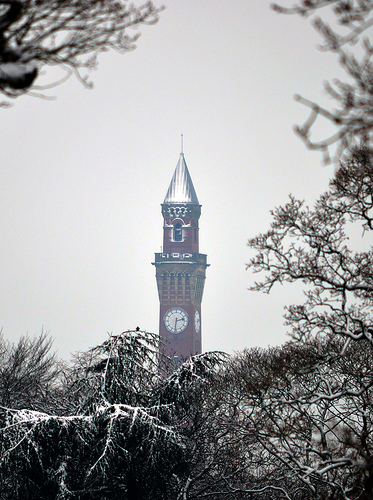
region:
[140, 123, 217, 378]
tall brick building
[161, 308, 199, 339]
two clocks on brick building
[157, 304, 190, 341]
clock on front of building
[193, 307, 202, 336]
clock on side of building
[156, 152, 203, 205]
spire of tall building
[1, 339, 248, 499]
snow covered branches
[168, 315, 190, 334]
hands of clock on front of building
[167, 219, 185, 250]
window on top of building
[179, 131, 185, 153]
bar sticking up from top of building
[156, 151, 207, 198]
snow covered roof of building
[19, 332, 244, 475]
Snow covering the trees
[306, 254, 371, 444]
Snow covering the trees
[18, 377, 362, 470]
Snow covering tree branches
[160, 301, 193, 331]
Clock on the tower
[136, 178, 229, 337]
Large brick tower with snow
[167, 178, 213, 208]
Snow covering the roof of the tower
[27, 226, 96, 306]
The sky is cloudy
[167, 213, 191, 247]
Very large window on tower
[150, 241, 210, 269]
Black balcony on the tower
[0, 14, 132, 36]
Snow covering tree branches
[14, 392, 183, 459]
White snow on some branches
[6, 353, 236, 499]
Some branchs of some trees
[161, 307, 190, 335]
A round and white clock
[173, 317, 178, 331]
The minute hand of a clock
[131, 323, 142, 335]
A small bird sitting on a tree branch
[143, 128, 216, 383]
a tall skinny red tower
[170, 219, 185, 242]
A window in a tower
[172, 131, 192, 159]
The top point of a tower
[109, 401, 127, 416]
A patch of white snow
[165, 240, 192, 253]
Red brick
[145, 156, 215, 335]
this is a tower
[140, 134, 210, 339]
the tower is tall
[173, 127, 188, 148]
this is an antennae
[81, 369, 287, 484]
this is a tree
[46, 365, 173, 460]
the trees have snow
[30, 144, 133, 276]
the sky is white in color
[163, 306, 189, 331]
this is a clock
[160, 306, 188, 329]
the clock is white in color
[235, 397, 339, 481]
the tree is branchy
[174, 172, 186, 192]
the roof is shiny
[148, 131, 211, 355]
tall clock tower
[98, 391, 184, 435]
snow covered tree branches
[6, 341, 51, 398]
tree with no leaves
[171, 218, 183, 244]
small arched window in tower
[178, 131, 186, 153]
spire on top of tower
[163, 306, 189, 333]
clock on clock tower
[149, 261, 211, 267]
ledge going around tower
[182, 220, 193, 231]
snow on ledge of tower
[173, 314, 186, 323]
hour hand on the clock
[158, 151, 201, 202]
roof on clock tower